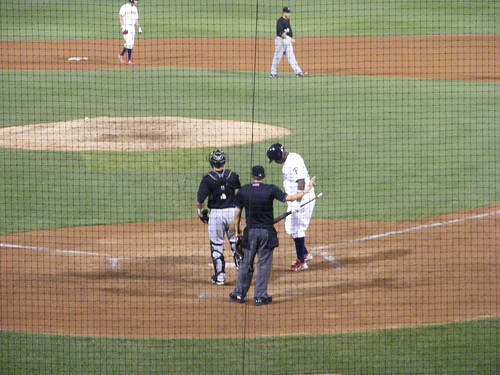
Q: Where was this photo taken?
A: Baseball stadium.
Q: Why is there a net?
A: Catch foul balls.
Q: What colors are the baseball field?
A: Brown, green.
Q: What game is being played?
A: Baseball.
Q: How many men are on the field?
A: Five.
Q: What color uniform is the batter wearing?
A: White.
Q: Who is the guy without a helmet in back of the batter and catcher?
A: Umpire.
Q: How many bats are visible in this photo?
A: One.